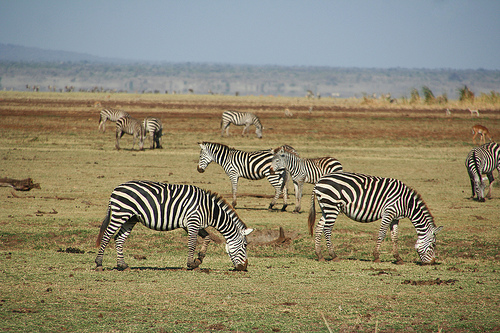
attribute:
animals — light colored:
[444, 103, 483, 118]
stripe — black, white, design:
[314, 178, 354, 201]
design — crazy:
[315, 172, 380, 208]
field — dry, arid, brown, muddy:
[0, 87, 500, 148]